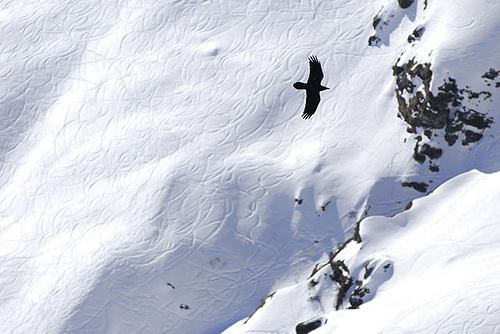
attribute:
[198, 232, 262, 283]
snow — white 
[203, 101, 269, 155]
lines — curved 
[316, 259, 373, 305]
rock — exposed 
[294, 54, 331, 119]
bird — flying , one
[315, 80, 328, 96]
beak — one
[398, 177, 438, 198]
rock — exposed 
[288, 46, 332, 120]
bird — black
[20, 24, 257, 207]
snow — some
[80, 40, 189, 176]
snow — white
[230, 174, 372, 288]
snow — white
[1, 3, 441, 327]
scene — with snow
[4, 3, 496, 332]
landscape — white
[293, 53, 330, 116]
bird — black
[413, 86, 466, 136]
spot — dry